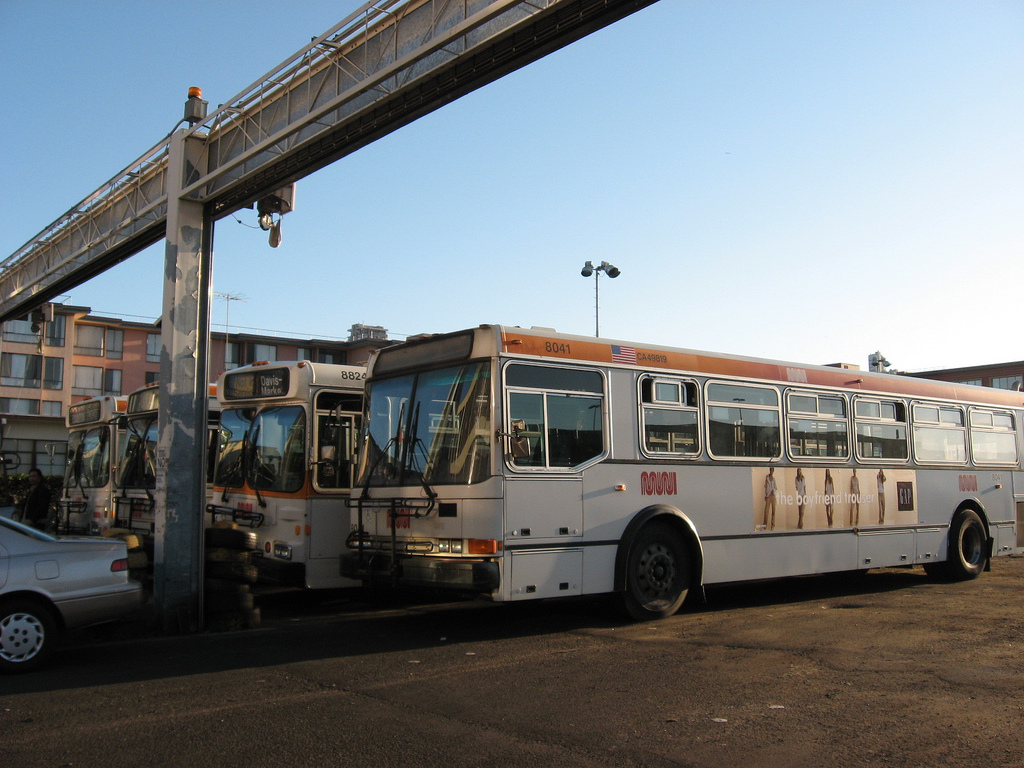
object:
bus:
[339, 324, 1024, 621]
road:
[0, 554, 1024, 768]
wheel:
[624, 526, 692, 620]